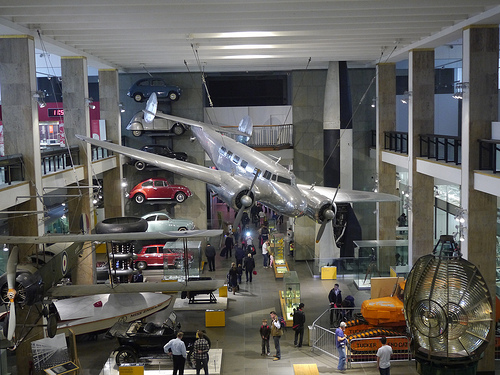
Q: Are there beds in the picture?
A: No, there are no beds.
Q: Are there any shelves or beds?
A: No, there are no beds or shelves.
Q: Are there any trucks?
A: No, there are no trucks.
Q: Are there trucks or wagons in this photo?
A: No, there are no trucks or wagons.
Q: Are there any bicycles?
A: No, there are no bicycles.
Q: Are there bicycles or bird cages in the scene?
A: No, there are no bicycles or bird cages.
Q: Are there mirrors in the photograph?
A: No, there are no mirrors.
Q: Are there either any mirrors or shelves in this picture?
A: No, there are no mirrors or shelves.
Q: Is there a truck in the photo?
A: No, there are no trucks.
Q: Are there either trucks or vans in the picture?
A: No, there are no trucks or vans.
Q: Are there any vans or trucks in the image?
A: No, there are no trucks or vans.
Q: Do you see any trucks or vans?
A: No, there are no trucks or vans.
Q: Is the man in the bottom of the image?
A: Yes, the man is in the bottom of the image.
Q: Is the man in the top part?
A: No, the man is in the bottom of the image.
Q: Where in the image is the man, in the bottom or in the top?
A: The man is in the bottom of the image.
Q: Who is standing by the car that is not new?
A: The man is standing by the car.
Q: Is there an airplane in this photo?
A: Yes, there is an airplane.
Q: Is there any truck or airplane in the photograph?
A: Yes, there is an airplane.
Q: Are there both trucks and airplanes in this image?
A: No, there is an airplane but no trucks.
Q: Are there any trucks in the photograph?
A: No, there are no trucks.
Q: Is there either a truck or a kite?
A: No, there are no trucks or kites.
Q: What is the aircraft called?
A: The aircraft is an airplane.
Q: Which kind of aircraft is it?
A: The aircraft is an airplane.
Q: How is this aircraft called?
A: This is an airplane.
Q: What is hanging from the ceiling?
A: The plane is hanging from the ceiling.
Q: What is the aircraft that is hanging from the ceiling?
A: The aircraft is an airplane.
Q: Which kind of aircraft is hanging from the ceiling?
A: The aircraft is an airplane.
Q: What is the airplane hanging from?
A: The airplane is hanging from the ceiling.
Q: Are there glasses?
A: No, there are no glasses.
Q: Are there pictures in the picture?
A: No, there are no pictures.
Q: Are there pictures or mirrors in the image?
A: No, there are no pictures or mirrors.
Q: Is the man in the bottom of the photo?
A: Yes, the man is in the bottom of the image.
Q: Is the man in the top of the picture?
A: No, the man is in the bottom of the image.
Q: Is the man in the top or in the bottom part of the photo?
A: The man is in the bottom of the image.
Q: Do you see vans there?
A: No, there are no vans.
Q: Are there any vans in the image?
A: No, there are no vans.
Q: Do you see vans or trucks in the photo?
A: No, there are no vans or trucks.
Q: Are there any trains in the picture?
A: No, there are no trains.